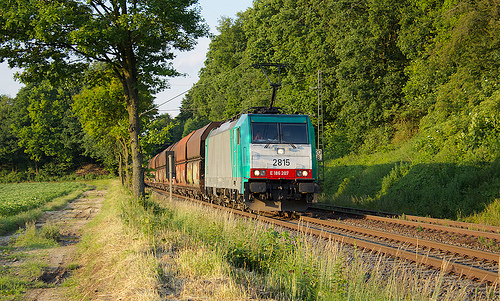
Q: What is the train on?
A: Tracks.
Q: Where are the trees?
A: Next to the train.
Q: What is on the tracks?
A: Train.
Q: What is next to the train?
A: A dirt road.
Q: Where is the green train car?
A: In front.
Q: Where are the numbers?
A: On the green car.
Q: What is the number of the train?
A: 2815.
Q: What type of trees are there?
A: Oak.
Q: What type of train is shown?
A: Cargo.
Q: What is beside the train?
A: Trees.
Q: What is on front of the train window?
A: Wipers.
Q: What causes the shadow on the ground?
A: Sunshine.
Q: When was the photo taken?
A: Afternoon.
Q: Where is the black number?
A: Middle of the first car.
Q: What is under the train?
A: Tracks.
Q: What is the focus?
A: Train passing by.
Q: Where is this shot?
A: Countryside.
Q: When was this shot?
A: Daytime.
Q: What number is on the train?
A: 2815.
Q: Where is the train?
A: Tracks.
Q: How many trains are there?
A: 1.